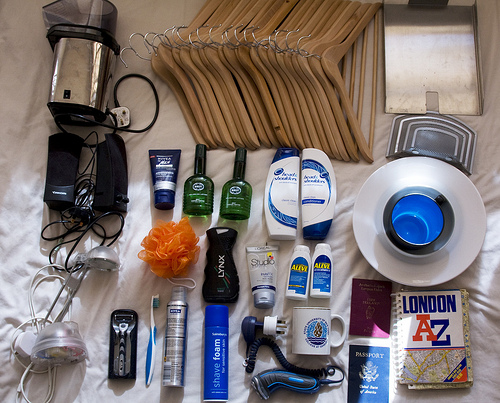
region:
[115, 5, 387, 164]
wooden v neck hangars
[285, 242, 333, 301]
two short white bottles with blue label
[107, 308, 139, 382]
a razor for legs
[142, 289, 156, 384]
a soft head toothbrush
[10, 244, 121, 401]
a small facial lamp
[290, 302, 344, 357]
a mouthwash cup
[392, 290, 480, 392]
a map of london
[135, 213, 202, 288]
a bright orange sponge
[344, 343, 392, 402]
a passport on bed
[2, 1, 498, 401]
all hygiene items on bed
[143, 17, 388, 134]
brown wooden hungers with silver hook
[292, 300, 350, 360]
A white and blue toothbrush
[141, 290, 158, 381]
A white and blue tooth brush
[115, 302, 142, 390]
A black shaving razor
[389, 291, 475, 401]
An AZ note book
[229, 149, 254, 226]
A green nail polish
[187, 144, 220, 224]
A green nail polish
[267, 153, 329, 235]
Two bottles of Head & Shoulders shampoo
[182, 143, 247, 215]
Two bottles of Brut aftershave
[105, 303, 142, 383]
Black and silver razor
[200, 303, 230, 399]
Blue can of shave foam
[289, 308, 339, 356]
White mug with blue design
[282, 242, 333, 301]
Two bottles of Aleve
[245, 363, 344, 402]
Blue electric razor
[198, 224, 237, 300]
Black bottle of Lynx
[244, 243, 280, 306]
Tube of Studio hair gel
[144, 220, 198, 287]
Orange loofah sponge with white hanger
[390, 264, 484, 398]
Planning trip London England.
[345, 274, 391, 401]
Necessary documents other countries.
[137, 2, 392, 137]
Wood closet garment hangers.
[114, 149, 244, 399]
Various personal hygiene toiletries.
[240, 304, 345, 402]
Body hair shaving implements.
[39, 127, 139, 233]
Small stereo music speakers.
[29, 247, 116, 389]
High intensity office lamp.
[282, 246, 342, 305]
Over-the-counter pain medication.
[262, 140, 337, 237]
Head and Shoulders shampoo conditioner.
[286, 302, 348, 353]
Favorite personal coffee mug.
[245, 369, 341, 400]
electric shaver on the sheet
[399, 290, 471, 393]
book of maps on the sheet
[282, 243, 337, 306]
two bottles of alieve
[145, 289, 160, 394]
blue and white toothbrush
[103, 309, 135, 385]
handheld razor on the sheet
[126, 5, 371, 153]
bunch of coat hangers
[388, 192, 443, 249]
inside of the blue cup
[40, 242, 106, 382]
lamp on the sheet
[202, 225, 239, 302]
shampoo bottle on the bed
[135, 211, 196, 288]
orange puffy on the bed